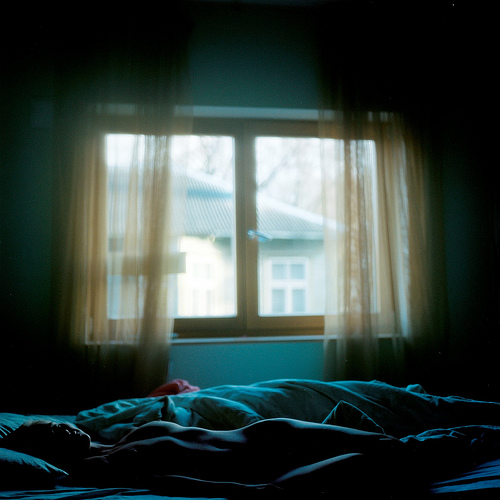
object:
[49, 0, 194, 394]
curtain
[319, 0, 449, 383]
curtain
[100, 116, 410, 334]
window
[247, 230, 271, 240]
handle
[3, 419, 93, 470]
head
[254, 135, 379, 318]
glass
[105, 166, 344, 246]
roof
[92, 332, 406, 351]
ledge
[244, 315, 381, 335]
home plate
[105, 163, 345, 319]
house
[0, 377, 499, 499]
bed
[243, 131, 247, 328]
gap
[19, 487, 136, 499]
sheet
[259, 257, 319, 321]
window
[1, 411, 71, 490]
pillow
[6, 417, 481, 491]
girl